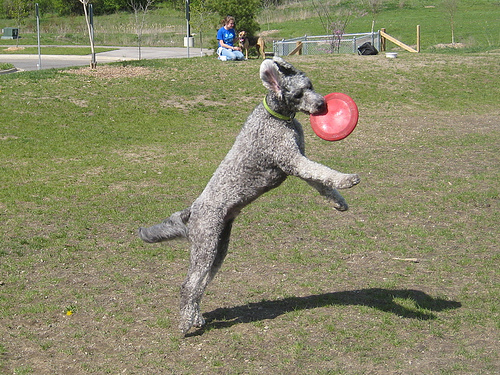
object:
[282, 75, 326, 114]
face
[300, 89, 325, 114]
mouth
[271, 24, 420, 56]
fence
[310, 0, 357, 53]
small tree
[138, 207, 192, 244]
tail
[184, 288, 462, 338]
shadow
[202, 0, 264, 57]
bush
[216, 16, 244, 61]
woman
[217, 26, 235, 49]
blue shirt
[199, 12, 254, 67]
woman ground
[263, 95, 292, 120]
collar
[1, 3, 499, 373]
park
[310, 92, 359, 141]
frisbee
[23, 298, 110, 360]
concrete area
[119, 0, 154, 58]
tree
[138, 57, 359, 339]
dog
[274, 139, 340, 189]
front legs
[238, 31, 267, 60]
dog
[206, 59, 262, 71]
ground